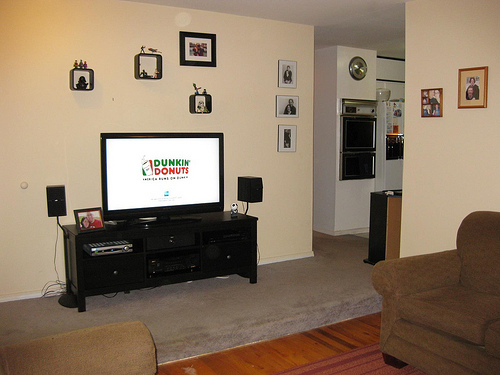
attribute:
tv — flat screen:
[102, 136, 223, 214]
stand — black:
[54, 209, 259, 315]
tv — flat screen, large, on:
[100, 131, 224, 221]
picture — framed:
[71, 206, 104, 231]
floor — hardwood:
[153, 309, 391, 373]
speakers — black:
[45, 174, 262, 215]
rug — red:
[276, 339, 436, 373]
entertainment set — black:
[59, 130, 259, 311]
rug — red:
[277, 340, 427, 372]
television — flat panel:
[77, 84, 261, 239]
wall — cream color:
[3, 5, 343, 308]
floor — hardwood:
[162, 297, 398, 371]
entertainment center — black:
[61, 201, 259, 311]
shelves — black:
[72, 51, 215, 111]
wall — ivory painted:
[0, 10, 316, 302]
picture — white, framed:
[270, 57, 296, 157]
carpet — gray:
[0, 251, 383, 372]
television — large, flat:
[99, 128, 231, 223]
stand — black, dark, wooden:
[61, 201, 261, 312]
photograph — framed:
[71, 201, 111, 231]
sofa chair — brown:
[0, 310, 163, 372]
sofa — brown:
[366, 197, 496, 373]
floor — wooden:
[159, 306, 419, 373]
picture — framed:
[173, 27, 218, 70]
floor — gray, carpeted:
[0, 232, 397, 371]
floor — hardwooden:
[156, 303, 404, 373]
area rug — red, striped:
[156, 287, 420, 373]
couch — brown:
[368, 202, 498, 368]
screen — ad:
[101, 130, 224, 219]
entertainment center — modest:
[59, 133, 259, 312]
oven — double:
[336, 96, 375, 181]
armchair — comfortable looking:
[371, 210, 499, 373]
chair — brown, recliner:
[369, 209, 499, 369]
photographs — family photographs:
[417, 64, 487, 115]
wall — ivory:
[398, 1, 497, 259]